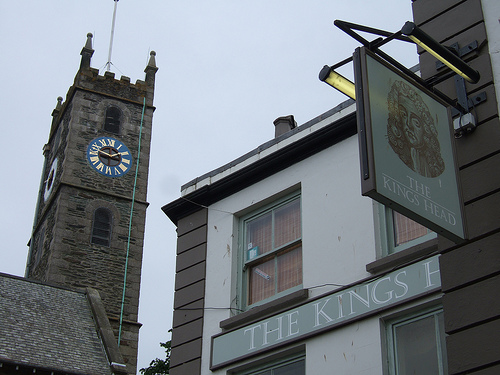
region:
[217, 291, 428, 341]
large white words on large sign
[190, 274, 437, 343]
big sign on front of building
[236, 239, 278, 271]
blue and white label in window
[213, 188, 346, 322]
large window in front of building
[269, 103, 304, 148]
chimney on top of building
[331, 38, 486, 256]
large silver sign on building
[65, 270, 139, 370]
gray edge of building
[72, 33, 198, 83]
pointed spirals on top of building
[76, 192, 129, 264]
curved window in building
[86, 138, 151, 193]
large round blue and yellow clock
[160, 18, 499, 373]
The Kings Head establishment.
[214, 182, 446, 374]
Four windows on the building.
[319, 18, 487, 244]
The Kings Head advertising sign hanging on the building.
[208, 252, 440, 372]
The Kings Head business sign between the windows.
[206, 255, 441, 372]
Sign for The Kings Head.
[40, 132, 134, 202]
White and blue clocks on the building's sides.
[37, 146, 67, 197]
White clock on the front of the building.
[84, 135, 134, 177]
Blue clock on the side of the building.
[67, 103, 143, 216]
Blue clock on the side of a gray building.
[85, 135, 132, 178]
Blue clock with white roman numerals.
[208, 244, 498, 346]
Sing that says "The Kings"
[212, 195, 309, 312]
Window on a building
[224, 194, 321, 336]
Blinds closed in a window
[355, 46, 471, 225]
Sign that says "The Kings Head"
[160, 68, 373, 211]
White roof on a building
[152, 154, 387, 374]
White and gray building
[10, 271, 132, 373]
Gray roof on a building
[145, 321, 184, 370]
Green leaves behind a building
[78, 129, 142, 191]
Clock on a tower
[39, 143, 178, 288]
Gray brick clock tower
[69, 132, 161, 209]
Blue outline on clock face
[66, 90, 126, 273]
Clock inside tall tower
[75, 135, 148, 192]
Roman numerals on clock face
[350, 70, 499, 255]
The kings head store sign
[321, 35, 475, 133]
Lights on both sides of sign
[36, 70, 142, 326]
Tower is made of rocks and bricks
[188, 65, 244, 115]
Sky is blue above building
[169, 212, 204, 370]
Building is gray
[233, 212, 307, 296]
Windows are blueish gray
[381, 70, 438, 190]
Man's face on sign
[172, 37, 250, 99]
part of the sky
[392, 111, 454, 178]
part of a banner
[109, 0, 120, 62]
part of a white pole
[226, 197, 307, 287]
a window on the building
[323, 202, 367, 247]
white part of the wall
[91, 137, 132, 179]
a big roman clock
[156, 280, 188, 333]
edge of a house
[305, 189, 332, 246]
white part of a wall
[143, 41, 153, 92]
one tip of the building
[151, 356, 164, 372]
part of a green branch